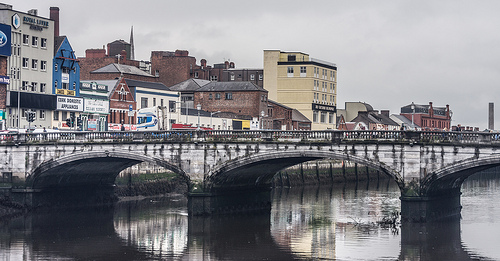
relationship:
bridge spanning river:
[0, 116, 471, 216] [1, 187, 498, 255]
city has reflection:
[7, 4, 483, 142] [0, 168, 500, 259]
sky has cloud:
[0, 1, 497, 131] [92, 10, 340, 84]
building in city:
[105, 25, 145, 61] [7, 4, 483, 142]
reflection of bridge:
[57, 187, 455, 239] [2, 125, 497, 195]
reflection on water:
[57, 187, 455, 239] [9, 170, 484, 254]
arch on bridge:
[37, 141, 194, 213] [3, 104, 498, 204]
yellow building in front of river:
[258, 47, 340, 121] [1, 174, 496, 258]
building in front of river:
[44, 5, 85, 133] [21, 163, 484, 255]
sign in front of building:
[52, 95, 84, 111] [7, 85, 112, 130]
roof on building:
[191, 78, 268, 94] [193, 79, 270, 130]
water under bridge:
[8, 164, 484, 251] [3, 124, 498, 178]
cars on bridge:
[350, 131, 410, 142] [12, 131, 484, 207]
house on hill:
[391, 100, 456, 134] [378, 125, 478, 148]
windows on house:
[419, 111, 452, 127] [391, 100, 456, 134]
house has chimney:
[342, 104, 404, 142] [381, 111, 391, 119]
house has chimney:
[342, 104, 404, 142] [355, 106, 375, 114]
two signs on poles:
[60, 60, 178, 150] [109, 96, 180, 131]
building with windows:
[58, 29, 395, 176] [140, 94, 180, 116]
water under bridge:
[2, 173, 498, 258] [1, 121, 498, 201]